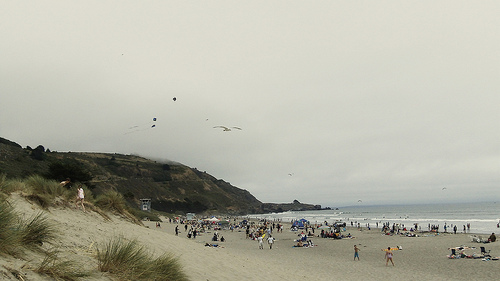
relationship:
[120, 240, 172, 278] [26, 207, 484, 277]
grass in sand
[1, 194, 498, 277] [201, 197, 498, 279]
sand on beach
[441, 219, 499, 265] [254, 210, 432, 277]
people laying on beach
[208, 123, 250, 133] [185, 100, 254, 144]
bird take flight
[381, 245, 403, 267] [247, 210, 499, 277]
person walking on beach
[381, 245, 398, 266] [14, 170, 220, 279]
person climbing dune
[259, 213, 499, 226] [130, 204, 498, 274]
wave moving towards beach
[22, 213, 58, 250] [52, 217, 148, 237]
grass in sand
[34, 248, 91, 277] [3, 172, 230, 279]
grass in sand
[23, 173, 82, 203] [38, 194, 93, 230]
grass in sand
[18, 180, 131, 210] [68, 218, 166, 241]
grass in sand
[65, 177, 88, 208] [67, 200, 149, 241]
people climbing up hill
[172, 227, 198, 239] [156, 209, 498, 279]
people standing on beach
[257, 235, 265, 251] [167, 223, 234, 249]
people standing on beach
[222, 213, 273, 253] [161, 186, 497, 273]
people standing on beach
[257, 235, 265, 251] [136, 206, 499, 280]
people standing on beach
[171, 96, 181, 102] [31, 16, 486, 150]
kite in sky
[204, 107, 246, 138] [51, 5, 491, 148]
bird in sky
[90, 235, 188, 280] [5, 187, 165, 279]
grass on dune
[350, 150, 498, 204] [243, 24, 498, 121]
clouds in sky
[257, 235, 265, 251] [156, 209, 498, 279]
people on beach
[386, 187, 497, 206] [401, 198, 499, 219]
sky meets ocean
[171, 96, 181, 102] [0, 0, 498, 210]
kite in sky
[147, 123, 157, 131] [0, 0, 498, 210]
kite in sky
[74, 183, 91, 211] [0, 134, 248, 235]
people on hillside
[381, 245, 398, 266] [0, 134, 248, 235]
person on hillside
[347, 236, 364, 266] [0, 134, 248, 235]
person on hillside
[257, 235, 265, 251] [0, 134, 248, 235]
people on hillside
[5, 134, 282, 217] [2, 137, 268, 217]
greenery on hill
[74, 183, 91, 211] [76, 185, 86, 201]
people in shirt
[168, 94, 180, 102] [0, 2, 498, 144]
kite flying in sky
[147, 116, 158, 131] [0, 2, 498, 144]
kite flying in sky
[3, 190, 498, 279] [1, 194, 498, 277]
beach covering sand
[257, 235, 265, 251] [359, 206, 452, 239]
people in ocean